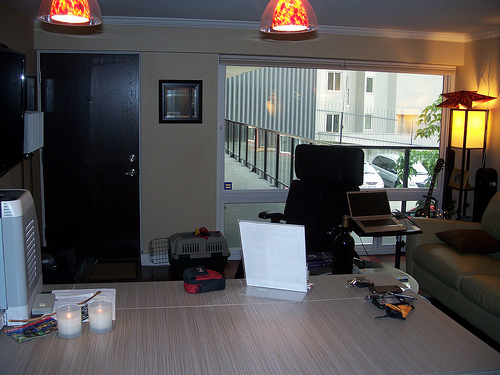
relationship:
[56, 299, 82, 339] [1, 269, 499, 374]
candle sitting on table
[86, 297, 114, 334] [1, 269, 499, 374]
candle sitting on table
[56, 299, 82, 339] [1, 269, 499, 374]
candle on table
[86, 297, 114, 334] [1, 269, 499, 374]
candle on table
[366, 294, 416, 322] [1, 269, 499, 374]
object on table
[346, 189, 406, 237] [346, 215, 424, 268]
laptop on table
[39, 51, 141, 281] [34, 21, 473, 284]
door on wall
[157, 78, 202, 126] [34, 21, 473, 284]
mirror hanging on wall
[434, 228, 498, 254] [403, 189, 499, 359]
pillow on couch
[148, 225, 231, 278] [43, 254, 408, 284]
pet carrier sitting on floor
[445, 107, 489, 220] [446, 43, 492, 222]
lamp in corner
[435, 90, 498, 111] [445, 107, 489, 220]
star on lamp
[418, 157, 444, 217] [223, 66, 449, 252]
guitar neck beside window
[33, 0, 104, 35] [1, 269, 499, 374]
light above table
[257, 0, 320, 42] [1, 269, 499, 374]
light above table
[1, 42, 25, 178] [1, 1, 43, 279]
tv on wall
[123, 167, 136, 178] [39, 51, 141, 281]
door handle on door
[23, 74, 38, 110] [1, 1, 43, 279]
picture frame hanging on wall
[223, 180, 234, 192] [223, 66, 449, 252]
sign on window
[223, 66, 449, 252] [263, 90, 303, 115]
window has a reflection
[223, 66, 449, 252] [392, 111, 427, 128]
window has a reflection